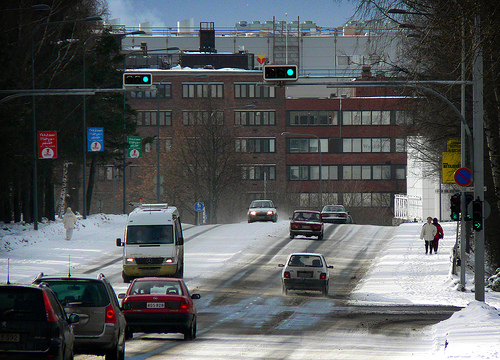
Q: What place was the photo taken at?
A: It was taken at the city.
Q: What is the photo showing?
A: It is showing a city.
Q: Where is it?
A: This is at the city.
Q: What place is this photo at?
A: It is at the city.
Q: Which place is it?
A: It is a city.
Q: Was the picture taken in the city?
A: Yes, it was taken in the city.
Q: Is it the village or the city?
A: It is the city.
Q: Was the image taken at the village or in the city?
A: It was taken at the city.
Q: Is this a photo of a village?
A: No, the picture is showing a city.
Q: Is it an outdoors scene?
A: Yes, it is outdoors.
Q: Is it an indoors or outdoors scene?
A: It is outdoors.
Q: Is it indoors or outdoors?
A: It is outdoors.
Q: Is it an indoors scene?
A: No, it is outdoors.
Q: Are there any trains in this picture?
A: No, there are no trains.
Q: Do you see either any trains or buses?
A: No, there are no trains or buses.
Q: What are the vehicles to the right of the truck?
A: The vehicles are cars.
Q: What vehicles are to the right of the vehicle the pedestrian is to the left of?
A: The vehicles are cars.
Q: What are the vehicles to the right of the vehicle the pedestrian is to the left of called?
A: The vehicles are cars.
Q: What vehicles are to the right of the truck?
A: The vehicles are cars.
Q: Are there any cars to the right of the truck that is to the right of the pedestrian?
A: Yes, there are cars to the right of the truck.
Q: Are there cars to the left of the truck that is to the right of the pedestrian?
A: No, the cars are to the right of the truck.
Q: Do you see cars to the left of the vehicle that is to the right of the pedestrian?
A: No, the cars are to the right of the truck.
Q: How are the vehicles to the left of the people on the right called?
A: The vehicles are cars.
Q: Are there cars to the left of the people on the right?
A: Yes, there are cars to the left of the people.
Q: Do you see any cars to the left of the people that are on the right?
A: Yes, there are cars to the left of the people.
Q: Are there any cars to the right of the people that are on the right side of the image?
A: No, the cars are to the left of the people.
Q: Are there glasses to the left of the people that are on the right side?
A: No, there are cars to the left of the people.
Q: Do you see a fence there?
A: No, there are no fences.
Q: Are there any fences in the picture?
A: No, there are no fences.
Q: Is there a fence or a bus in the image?
A: No, there are no fences or buses.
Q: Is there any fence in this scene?
A: No, there are no fences.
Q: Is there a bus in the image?
A: No, there are no buses.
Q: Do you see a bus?
A: No, there are no buses.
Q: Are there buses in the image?
A: No, there are no buses.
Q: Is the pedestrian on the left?
A: Yes, the pedestrian is on the left of the image.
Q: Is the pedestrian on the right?
A: No, the pedestrian is on the left of the image.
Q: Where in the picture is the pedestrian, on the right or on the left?
A: The pedestrian is on the left of the image.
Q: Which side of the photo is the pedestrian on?
A: The pedestrian is on the left of the image.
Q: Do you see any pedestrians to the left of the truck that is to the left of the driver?
A: Yes, there is a pedestrian to the left of the truck.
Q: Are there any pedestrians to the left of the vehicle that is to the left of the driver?
A: Yes, there is a pedestrian to the left of the truck.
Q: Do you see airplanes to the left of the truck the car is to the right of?
A: No, there is a pedestrian to the left of the truck.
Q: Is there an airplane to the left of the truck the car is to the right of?
A: No, there is a pedestrian to the left of the truck.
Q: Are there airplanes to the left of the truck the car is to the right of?
A: No, there is a pedestrian to the left of the truck.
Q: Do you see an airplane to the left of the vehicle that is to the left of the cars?
A: No, there is a pedestrian to the left of the truck.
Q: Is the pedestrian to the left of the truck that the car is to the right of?
A: Yes, the pedestrian is to the left of the truck.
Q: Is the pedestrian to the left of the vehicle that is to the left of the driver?
A: Yes, the pedestrian is to the left of the truck.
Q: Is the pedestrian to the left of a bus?
A: No, the pedestrian is to the left of the truck.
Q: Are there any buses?
A: No, there are no buses.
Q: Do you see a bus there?
A: No, there are no buses.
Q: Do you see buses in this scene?
A: No, there are no buses.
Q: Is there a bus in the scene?
A: No, there are no buses.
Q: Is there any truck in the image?
A: Yes, there is a truck.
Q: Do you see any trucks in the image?
A: Yes, there is a truck.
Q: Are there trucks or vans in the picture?
A: Yes, there is a truck.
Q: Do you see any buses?
A: No, there are no buses.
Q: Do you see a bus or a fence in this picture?
A: No, there are no buses or fences.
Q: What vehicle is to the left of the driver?
A: The vehicle is a truck.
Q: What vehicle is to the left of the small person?
A: The vehicle is a truck.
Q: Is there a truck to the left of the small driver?
A: Yes, there is a truck to the left of the driver.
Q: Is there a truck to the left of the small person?
A: Yes, there is a truck to the left of the driver.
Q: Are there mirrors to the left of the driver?
A: No, there is a truck to the left of the driver.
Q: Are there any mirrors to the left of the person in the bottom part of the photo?
A: No, there is a truck to the left of the driver.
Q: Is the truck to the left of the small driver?
A: Yes, the truck is to the left of the driver.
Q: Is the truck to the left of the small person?
A: Yes, the truck is to the left of the driver.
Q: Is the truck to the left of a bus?
A: No, the truck is to the left of the driver.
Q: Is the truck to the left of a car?
A: Yes, the truck is to the left of a car.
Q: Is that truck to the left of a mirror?
A: No, the truck is to the left of a car.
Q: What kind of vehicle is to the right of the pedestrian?
A: The vehicle is a truck.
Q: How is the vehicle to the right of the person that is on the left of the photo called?
A: The vehicle is a truck.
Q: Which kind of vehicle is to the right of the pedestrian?
A: The vehicle is a truck.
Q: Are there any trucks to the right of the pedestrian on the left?
A: Yes, there is a truck to the right of the pedestrian.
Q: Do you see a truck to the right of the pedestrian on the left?
A: Yes, there is a truck to the right of the pedestrian.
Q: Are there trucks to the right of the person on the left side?
A: Yes, there is a truck to the right of the pedestrian.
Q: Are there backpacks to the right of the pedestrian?
A: No, there is a truck to the right of the pedestrian.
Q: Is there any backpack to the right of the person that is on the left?
A: No, there is a truck to the right of the pedestrian.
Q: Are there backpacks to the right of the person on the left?
A: No, there is a truck to the right of the pedestrian.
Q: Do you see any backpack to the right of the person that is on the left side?
A: No, there is a truck to the right of the pedestrian.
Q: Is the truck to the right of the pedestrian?
A: Yes, the truck is to the right of the pedestrian.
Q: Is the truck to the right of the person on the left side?
A: Yes, the truck is to the right of the pedestrian.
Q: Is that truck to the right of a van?
A: No, the truck is to the right of the pedestrian.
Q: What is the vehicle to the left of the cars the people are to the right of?
A: The vehicle is a truck.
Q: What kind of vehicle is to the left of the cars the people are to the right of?
A: The vehicle is a truck.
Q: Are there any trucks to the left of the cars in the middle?
A: Yes, there is a truck to the left of the cars.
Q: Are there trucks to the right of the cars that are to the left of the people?
A: No, the truck is to the left of the cars.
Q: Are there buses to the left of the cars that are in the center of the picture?
A: No, there is a truck to the left of the cars.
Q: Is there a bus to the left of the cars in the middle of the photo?
A: No, there is a truck to the left of the cars.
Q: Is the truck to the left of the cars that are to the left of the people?
A: Yes, the truck is to the left of the cars.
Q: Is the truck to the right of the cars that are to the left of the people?
A: No, the truck is to the left of the cars.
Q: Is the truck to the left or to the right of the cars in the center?
A: The truck is to the left of the cars.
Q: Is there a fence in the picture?
A: No, there are no fences.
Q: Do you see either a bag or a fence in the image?
A: No, there are no fences or bags.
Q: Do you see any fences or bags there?
A: No, there are no fences or bags.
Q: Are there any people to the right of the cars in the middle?
A: Yes, there are people to the right of the cars.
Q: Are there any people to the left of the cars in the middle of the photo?
A: No, the people are to the right of the cars.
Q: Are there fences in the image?
A: No, there are no fences.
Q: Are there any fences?
A: No, there are no fences.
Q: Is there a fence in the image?
A: No, there are no fences.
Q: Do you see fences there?
A: No, there are no fences.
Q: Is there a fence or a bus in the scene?
A: No, there are no fences or buses.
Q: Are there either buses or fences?
A: No, there are no fences or buses.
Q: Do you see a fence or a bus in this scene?
A: No, there are no fences or buses.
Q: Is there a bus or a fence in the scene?
A: No, there are no fences or buses.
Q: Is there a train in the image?
A: No, there are no trains.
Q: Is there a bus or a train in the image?
A: No, there are no trains or buses.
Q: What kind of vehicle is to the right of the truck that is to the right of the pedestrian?
A: The vehicle is a car.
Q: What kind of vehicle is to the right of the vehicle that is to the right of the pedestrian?
A: The vehicle is a car.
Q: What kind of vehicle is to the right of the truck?
A: The vehicle is a car.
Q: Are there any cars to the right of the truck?
A: Yes, there is a car to the right of the truck.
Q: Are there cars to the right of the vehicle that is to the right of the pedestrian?
A: Yes, there is a car to the right of the truck.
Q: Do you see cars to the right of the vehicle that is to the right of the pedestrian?
A: Yes, there is a car to the right of the truck.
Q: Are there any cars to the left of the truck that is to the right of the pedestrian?
A: No, the car is to the right of the truck.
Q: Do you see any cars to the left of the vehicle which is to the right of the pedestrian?
A: No, the car is to the right of the truck.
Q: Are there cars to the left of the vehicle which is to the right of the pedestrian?
A: No, the car is to the right of the truck.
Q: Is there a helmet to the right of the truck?
A: No, there is a car to the right of the truck.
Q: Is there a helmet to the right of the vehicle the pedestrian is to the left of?
A: No, there is a car to the right of the truck.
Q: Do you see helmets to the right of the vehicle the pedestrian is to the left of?
A: No, there is a car to the right of the truck.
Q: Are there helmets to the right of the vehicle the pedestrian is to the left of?
A: No, there is a car to the right of the truck.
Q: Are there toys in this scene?
A: No, there are no toys.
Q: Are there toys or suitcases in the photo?
A: No, there are no toys or suitcases.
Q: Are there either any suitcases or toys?
A: No, there are no toys or suitcases.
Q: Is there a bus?
A: No, there are no buses.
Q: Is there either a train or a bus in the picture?
A: No, there are no buses or trains.